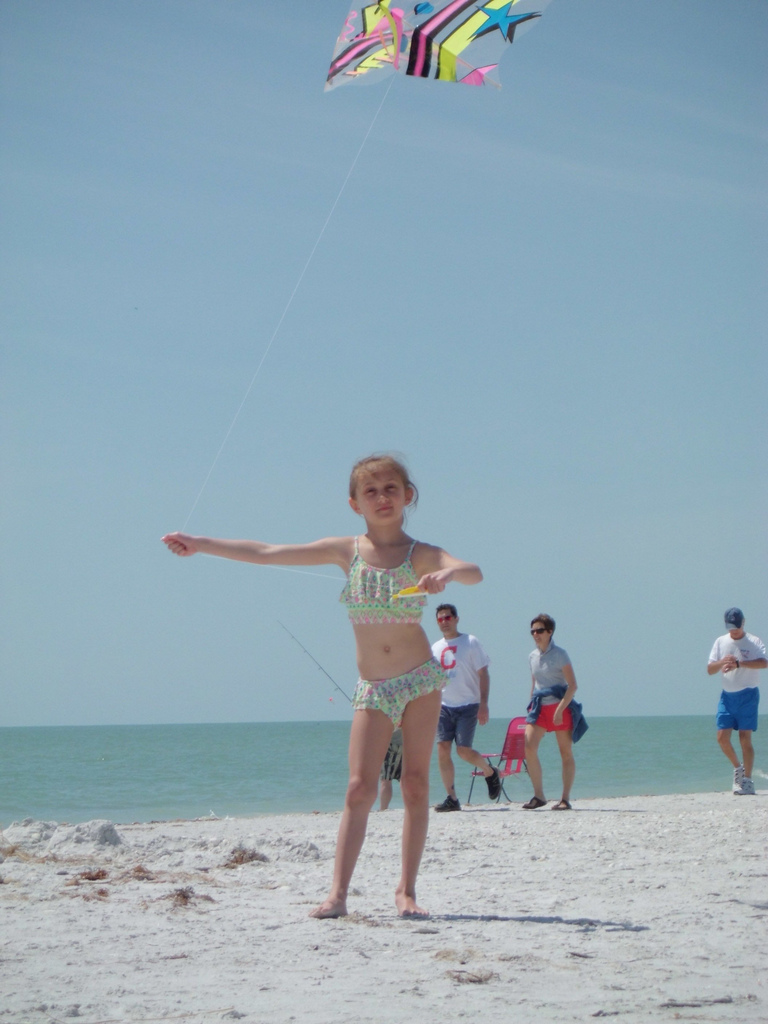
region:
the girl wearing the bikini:
[162, 446, 484, 917]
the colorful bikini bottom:
[347, 658, 446, 731]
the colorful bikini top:
[334, 534, 429, 626]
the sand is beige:
[2, 789, 766, 1019]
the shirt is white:
[707, 630, 766, 692]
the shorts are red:
[529, 703, 571, 732]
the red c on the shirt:
[427, 631, 486, 707]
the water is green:
[0, 712, 766, 828]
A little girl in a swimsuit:
[164, 455, 484, 925]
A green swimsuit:
[341, 538, 447, 720]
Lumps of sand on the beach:
[0, 805, 255, 908]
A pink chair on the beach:
[469, 714, 529, 805]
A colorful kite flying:
[325, 0, 538, 94]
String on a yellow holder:
[387, 581, 434, 600]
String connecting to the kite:
[164, 72, 434, 537]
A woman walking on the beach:
[522, 606, 581, 808]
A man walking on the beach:
[424, 605, 497, 810]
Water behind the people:
[0, 707, 766, 820]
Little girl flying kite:
[170, 451, 521, 921]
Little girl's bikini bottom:
[348, 653, 457, 727]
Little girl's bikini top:
[335, 535, 438, 632]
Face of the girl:
[345, 452, 421, 536]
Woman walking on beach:
[520, 609, 600, 820]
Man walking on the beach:
[432, 597, 514, 816]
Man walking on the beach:
[696, 603, 765, 797]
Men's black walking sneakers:
[435, 768, 511, 817]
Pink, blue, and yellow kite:
[314, 0, 544, 105]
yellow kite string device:
[394, 570, 437, 607]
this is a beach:
[74, 38, 587, 816]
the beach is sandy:
[122, 839, 321, 964]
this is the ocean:
[50, 732, 212, 813]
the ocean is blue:
[68, 741, 206, 789]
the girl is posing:
[254, 525, 574, 935]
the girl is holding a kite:
[166, 141, 580, 838]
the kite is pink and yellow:
[313, 14, 523, 145]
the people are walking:
[460, 501, 760, 882]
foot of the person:
[400, 886, 437, 923]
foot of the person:
[430, 793, 464, 813]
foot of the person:
[488, 777, 503, 797]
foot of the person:
[525, 787, 549, 810]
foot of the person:
[732, 779, 757, 791]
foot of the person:
[380, 794, 397, 803]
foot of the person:
[368, 803, 386, 812]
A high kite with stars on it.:
[327, 0, 550, 91]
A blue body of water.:
[0, 717, 766, 832]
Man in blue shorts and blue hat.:
[705, 607, 767, 796]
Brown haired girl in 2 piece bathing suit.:
[159, 452, 485, 919]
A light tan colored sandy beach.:
[1, 790, 765, 1022]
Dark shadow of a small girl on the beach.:
[397, 912, 649, 932]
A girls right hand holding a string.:
[161, 529, 199, 557]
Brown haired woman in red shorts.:
[520, 612, 578, 810]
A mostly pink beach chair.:
[468, 714, 534, 807]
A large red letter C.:
[440, 643, 457, 671]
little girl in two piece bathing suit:
[163, 453, 486, 924]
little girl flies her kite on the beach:
[169, 449, 477, 930]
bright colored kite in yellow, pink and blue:
[307, 0, 563, 100]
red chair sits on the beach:
[461, 705, 531, 818]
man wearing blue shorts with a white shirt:
[704, 605, 764, 801]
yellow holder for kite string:
[390, 577, 439, 614]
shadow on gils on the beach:
[402, 906, 649, 935]